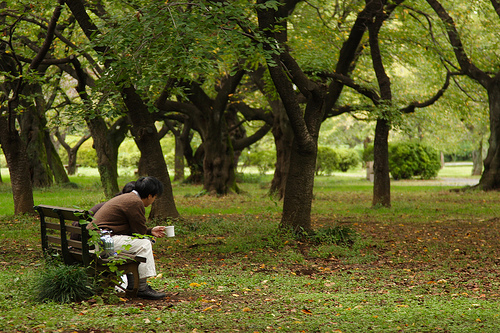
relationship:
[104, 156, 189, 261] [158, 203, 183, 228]
man holds cup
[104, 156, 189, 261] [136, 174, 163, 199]
man has hair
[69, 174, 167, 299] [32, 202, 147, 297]
couple sitting bench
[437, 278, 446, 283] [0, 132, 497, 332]
leaf on floor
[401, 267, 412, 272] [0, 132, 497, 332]
leaf on floor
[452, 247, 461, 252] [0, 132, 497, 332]
leaf on floor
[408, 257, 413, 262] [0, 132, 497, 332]
leaf on floor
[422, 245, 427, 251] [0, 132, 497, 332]
leaf on floor